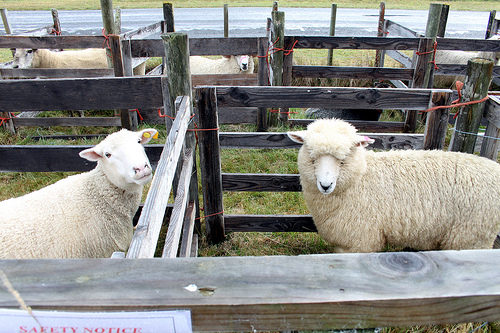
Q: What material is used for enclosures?
A: Wood.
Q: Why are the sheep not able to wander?
A: Fencing.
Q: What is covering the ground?
A: Grass.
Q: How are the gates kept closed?
A: Red string.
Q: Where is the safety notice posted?
A: On fence.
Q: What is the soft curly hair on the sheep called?
A: Wool.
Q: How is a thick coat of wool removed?
A: Shaved off.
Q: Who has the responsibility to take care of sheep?
A: Shepherd.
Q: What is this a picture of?
A: A series of outdoor wooden pens, with sheep in them.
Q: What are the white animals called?
A: Sheep.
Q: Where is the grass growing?
A: Inside the pens.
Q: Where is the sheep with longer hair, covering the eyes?
A: In the front, inside the pen, on the right.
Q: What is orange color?
A: Twine.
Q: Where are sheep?
A: In pen.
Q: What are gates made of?
A: Wood.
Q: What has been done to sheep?
A: Sheared.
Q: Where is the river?
A: Behind pens.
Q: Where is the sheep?
A: In pens.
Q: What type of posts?
A: Wooden.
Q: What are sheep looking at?
A: Camera.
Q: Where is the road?
A: Behind pens.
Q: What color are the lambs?
A: White.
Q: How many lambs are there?
A: Four.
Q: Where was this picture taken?
A: A farm.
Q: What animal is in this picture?
A: Lamb.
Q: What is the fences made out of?
A: Wood.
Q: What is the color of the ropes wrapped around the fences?
A: Orange.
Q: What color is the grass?
A: Green.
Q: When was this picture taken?
A: Daytime.